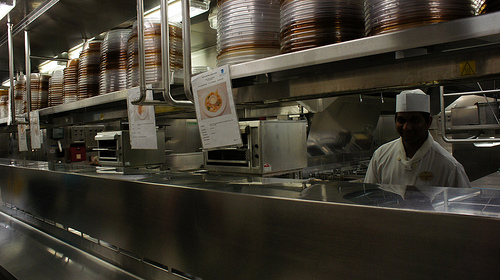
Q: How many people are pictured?
A: One.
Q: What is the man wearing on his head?
A: Hat.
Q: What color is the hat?
A: White.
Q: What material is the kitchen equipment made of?
A: Metal.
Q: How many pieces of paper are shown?
A: Four.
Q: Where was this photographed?
A: Kitchen.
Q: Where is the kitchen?
A: A restaurant.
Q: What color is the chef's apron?
A: White.